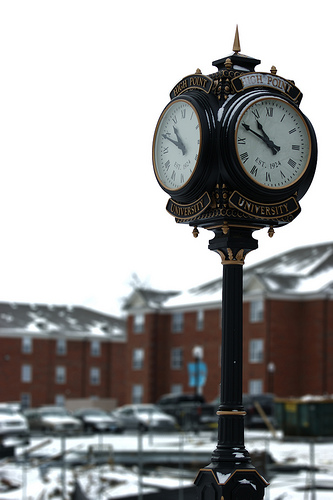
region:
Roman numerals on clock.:
[235, 90, 319, 187]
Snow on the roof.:
[163, 276, 218, 312]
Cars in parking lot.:
[42, 389, 159, 445]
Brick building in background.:
[50, 337, 117, 393]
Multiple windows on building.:
[10, 328, 114, 403]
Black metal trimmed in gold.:
[157, 31, 304, 252]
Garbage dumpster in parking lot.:
[264, 383, 330, 452]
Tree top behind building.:
[117, 253, 162, 326]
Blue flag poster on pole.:
[181, 353, 222, 406]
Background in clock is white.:
[152, 97, 218, 190]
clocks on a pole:
[143, 21, 331, 498]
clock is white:
[227, 85, 317, 203]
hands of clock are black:
[238, 115, 286, 159]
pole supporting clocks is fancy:
[189, 230, 276, 499]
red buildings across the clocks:
[8, 238, 331, 433]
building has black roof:
[0, 293, 137, 337]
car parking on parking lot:
[1, 383, 262, 444]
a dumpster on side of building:
[274, 386, 331, 449]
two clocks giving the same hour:
[146, 88, 317, 208]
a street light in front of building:
[183, 334, 212, 433]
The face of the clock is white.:
[229, 90, 313, 188]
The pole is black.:
[207, 229, 277, 498]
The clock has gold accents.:
[158, 48, 303, 498]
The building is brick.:
[3, 295, 323, 409]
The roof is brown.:
[6, 260, 330, 318]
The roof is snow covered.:
[18, 248, 328, 351]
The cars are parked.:
[7, 390, 275, 452]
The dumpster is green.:
[277, 390, 330, 437]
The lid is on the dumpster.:
[276, 386, 331, 437]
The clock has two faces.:
[150, 53, 318, 231]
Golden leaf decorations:
[216, 247, 248, 263]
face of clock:
[232, 90, 313, 195]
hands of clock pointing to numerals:
[238, 120, 283, 154]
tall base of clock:
[187, 233, 276, 499]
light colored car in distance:
[107, 400, 181, 433]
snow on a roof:
[9, 303, 120, 334]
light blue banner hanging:
[184, 360, 207, 391]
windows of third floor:
[14, 337, 105, 357]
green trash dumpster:
[270, 394, 332, 439]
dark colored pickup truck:
[152, 393, 221, 431]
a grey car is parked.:
[113, 393, 175, 428]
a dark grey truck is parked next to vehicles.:
[151, 377, 219, 420]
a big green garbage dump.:
[266, 386, 328, 432]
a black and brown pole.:
[190, 225, 261, 487]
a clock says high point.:
[224, 62, 300, 91]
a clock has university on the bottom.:
[225, 185, 305, 226]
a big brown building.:
[0, 270, 219, 396]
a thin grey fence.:
[140, 398, 214, 448]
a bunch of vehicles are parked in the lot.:
[0, 388, 220, 439]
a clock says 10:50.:
[208, 63, 332, 212]